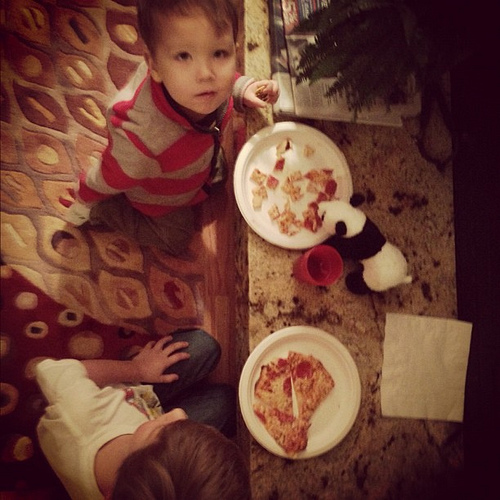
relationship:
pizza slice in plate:
[288, 348, 335, 419] [238, 324, 361, 458]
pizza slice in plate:
[252, 357, 294, 417] [238, 324, 361, 458]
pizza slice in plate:
[251, 402, 312, 459] [238, 324, 361, 458]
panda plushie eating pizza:
[309, 190, 419, 298] [247, 141, 338, 231]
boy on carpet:
[32, 326, 250, 500] [1, 0, 201, 340]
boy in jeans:
[32, 333, 243, 499] [152, 326, 237, 436]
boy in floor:
[32, 333, 243, 499] [1, 1, 235, 495]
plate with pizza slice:
[219, 317, 373, 458] [283, 349, 335, 426]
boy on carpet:
[98, 10, 250, 248] [0, 0, 240, 495]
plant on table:
[291, 0, 447, 123] [228, 207, 470, 355]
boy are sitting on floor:
[56, 0, 282, 257] [1, 1, 235, 495]